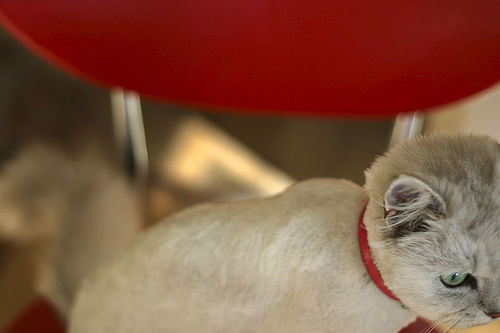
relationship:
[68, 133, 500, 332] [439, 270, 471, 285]
cat has eye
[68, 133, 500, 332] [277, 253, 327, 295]
cat has fur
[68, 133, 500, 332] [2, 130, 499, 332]
cat has fur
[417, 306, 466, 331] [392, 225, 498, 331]
whiskers protruding from face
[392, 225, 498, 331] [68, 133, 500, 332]
face of cat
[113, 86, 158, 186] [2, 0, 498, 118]
support for chair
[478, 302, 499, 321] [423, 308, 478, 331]
nose next to whiskers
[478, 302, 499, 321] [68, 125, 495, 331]
nose of cat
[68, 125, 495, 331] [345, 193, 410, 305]
cat wearing collar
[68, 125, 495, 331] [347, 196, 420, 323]
cat wearing collar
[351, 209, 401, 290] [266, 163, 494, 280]
collar on cat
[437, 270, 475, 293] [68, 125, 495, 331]
eye on cat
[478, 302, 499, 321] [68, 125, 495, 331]
nose on cat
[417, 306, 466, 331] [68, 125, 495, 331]
whiskers on cat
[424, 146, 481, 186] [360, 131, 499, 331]
fur on head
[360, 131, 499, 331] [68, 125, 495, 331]
head of cat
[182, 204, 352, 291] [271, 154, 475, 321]
fur on cat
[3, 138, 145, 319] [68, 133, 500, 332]
tail on cat